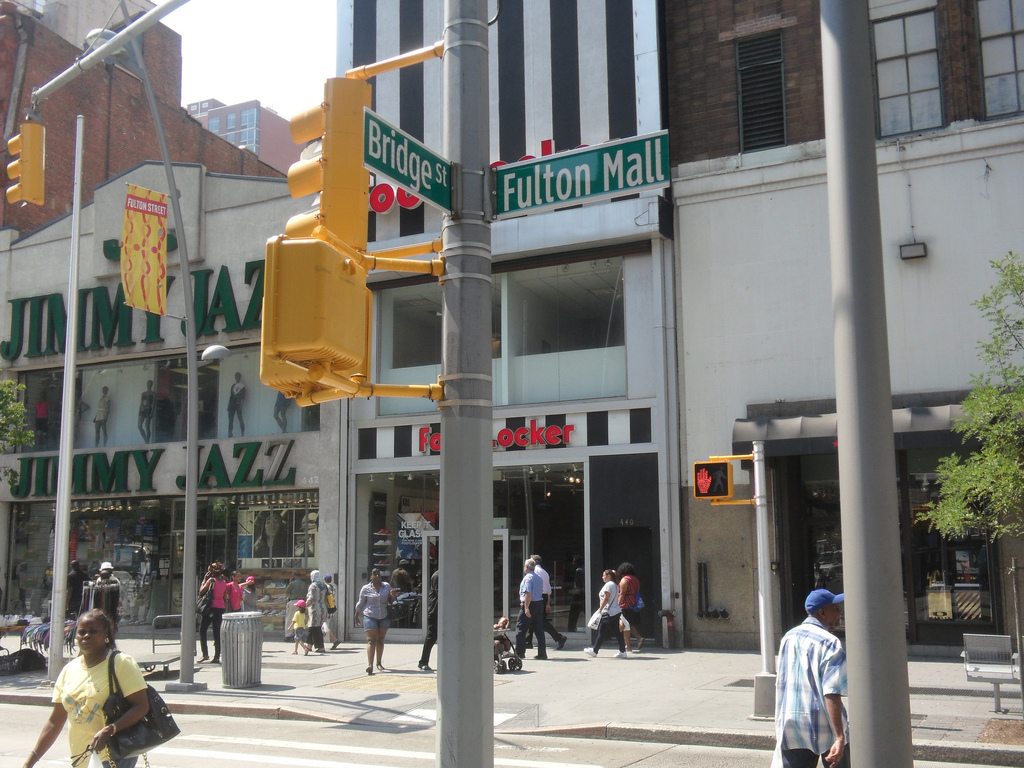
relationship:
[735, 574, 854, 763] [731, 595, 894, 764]
man in shirt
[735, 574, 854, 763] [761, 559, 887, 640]
man in cap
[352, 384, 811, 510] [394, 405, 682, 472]
sign with letters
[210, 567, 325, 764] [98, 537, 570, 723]
can on sidewalk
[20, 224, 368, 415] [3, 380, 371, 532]
sign above one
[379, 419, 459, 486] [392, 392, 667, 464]
letter in footlocker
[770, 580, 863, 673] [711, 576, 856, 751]
head of man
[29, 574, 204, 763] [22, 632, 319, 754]
woman with shirt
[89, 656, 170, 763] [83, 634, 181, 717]
object around shoulder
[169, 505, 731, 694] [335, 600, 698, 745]
people on sidewalk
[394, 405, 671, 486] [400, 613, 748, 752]
words above ground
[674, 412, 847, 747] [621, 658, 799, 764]
pole next to street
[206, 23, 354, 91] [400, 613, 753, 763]
sky above ground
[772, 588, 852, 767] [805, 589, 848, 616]
man wearing cap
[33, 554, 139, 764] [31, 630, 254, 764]
woman wearing shirt